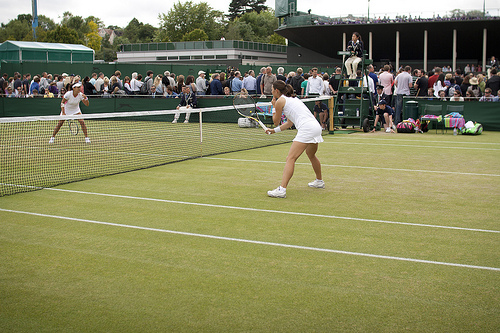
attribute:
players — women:
[47, 80, 326, 198]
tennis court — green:
[1, 120, 497, 273]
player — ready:
[46, 83, 92, 145]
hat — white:
[71, 83, 82, 92]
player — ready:
[234, 79, 325, 197]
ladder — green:
[326, 50, 377, 131]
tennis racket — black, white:
[232, 91, 268, 136]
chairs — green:
[417, 104, 467, 134]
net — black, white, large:
[1, 96, 334, 197]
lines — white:
[1, 122, 494, 272]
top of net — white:
[1, 95, 331, 125]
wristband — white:
[273, 126, 282, 134]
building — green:
[0, 40, 95, 64]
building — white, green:
[116, 40, 286, 62]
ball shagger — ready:
[368, 99, 396, 133]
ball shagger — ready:
[308, 100, 328, 129]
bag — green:
[456, 120, 484, 136]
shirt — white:
[60, 90, 87, 110]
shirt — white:
[278, 95, 317, 128]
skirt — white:
[293, 122, 326, 145]